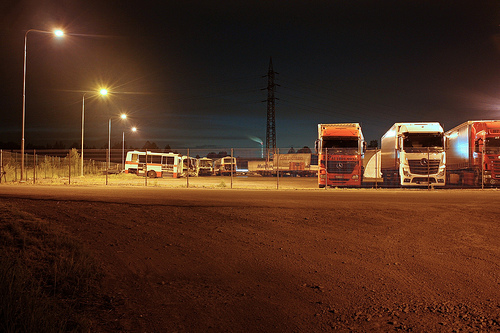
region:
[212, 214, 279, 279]
part of a ground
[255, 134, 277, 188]
part of a fecne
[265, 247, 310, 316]
part of a ground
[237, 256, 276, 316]
part of a ground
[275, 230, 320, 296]
part of a ground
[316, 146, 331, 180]
part of a post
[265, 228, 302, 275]
part of a ground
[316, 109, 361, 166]
part of a window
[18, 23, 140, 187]
Row of Brightly Lit Street Lights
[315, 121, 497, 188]
Row Of Semi-Trucks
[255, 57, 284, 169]
Tall Power Line in the distance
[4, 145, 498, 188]
Chainlink Fence Surrounding The Lot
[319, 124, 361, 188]
Bright Orange Semi Truck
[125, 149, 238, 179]
Group of Small white and orange buses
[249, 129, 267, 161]
Smoke coming from an industrial chimney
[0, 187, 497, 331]
Brown Rich Soil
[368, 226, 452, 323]
Tire Tracks Left In The Dirt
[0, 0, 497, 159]
Dark Nighttime Sky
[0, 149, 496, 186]
A parking lot with a fence around it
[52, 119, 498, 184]
Various types trucks parked in a parking lot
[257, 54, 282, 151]
Tall black electrical transmission tower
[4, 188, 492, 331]
Brown dirt road with small stones on it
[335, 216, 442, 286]
Tire tracks in the dirt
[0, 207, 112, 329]
Small patch of grass with dirt next to it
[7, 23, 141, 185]
Row of light poles with flood lights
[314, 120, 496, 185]
A red and a whit tractor trailers parked behind a metal fence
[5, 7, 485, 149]
A dark sky with lots of clouds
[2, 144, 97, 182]
Fence with weeds along it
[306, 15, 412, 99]
sky above the trucks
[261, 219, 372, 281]
dirt on the ground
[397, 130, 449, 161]
window on front of truck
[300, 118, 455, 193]
orange and white trucks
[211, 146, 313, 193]
fence in front of trucks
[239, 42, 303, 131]
metal pole in the background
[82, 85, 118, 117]
light on a pole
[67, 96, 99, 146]
pole under a light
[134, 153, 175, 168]
windows on vehicle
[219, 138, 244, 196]
pole of the fence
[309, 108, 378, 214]
the truck is parked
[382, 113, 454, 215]
the truck is parked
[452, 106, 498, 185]
the truck is parked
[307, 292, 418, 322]
dirt on the ground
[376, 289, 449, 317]
dirt on the ground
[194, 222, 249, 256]
dirt on the ground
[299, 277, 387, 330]
dirt on the ground